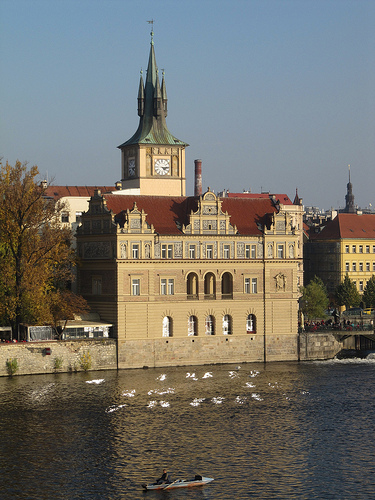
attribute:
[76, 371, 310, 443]
objects — white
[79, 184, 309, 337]
building — large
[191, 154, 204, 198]
chimney — tall, red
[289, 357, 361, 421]
water — turbulent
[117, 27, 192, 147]
roof — green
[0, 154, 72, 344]
tree — large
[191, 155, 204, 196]
stack — smoke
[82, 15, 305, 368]
building — large